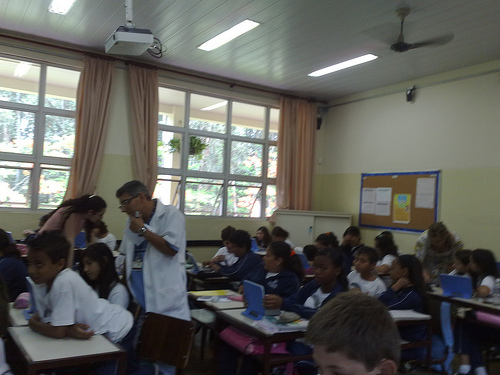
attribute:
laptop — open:
[238, 266, 270, 324]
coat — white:
[142, 204, 212, 330]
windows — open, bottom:
[190, 92, 279, 213]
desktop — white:
[211, 313, 296, 358]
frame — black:
[220, 313, 262, 338]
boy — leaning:
[13, 230, 162, 335]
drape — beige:
[70, 65, 116, 195]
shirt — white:
[55, 275, 115, 328]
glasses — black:
[118, 194, 157, 212]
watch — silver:
[139, 217, 149, 246]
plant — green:
[155, 130, 234, 165]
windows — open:
[224, 119, 264, 218]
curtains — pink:
[273, 101, 330, 201]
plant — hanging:
[164, 125, 212, 162]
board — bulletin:
[354, 165, 447, 244]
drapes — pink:
[274, 92, 320, 215]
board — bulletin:
[351, 169, 446, 233]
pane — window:
[227, 136, 263, 178]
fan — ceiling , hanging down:
[367, 15, 456, 65]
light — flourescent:
[301, 40, 391, 81]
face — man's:
[114, 185, 149, 220]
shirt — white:
[32, 268, 137, 336]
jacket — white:
[112, 197, 198, 327]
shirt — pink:
[30, 199, 81, 234]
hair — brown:
[210, 214, 495, 264]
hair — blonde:
[302, 280, 409, 367]